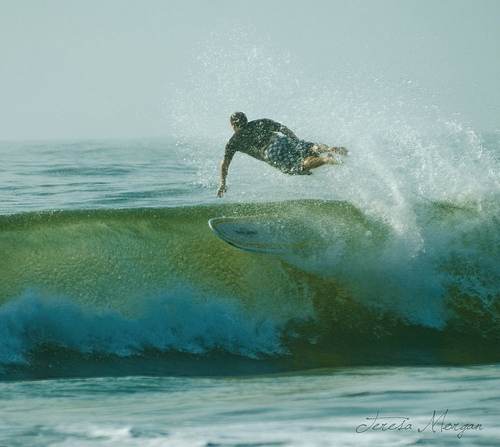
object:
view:
[15, 20, 181, 131]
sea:
[406, 129, 479, 218]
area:
[0, 135, 499, 208]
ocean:
[0, 243, 500, 369]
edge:
[208, 217, 255, 250]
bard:
[178, 210, 352, 301]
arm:
[220, 146, 239, 182]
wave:
[292, 194, 370, 240]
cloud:
[0, 30, 499, 75]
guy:
[214, 110, 354, 199]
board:
[206, 211, 355, 254]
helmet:
[230, 112, 248, 125]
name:
[354, 409, 483, 441]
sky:
[0, 0, 500, 100]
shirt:
[223, 118, 282, 160]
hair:
[229, 110, 248, 130]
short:
[263, 135, 314, 177]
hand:
[216, 183, 228, 198]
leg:
[330, 146, 350, 158]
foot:
[324, 152, 346, 166]